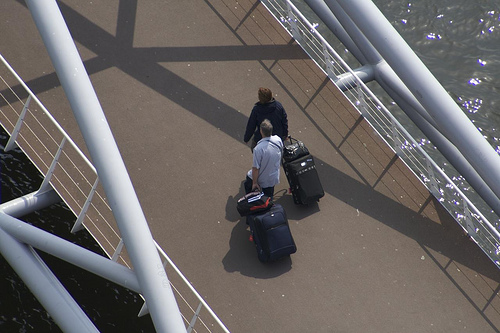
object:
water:
[290, 0, 499, 237]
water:
[0, 124, 157, 333]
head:
[258, 118, 274, 137]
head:
[257, 86, 274, 105]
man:
[241, 84, 290, 155]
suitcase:
[282, 152, 327, 207]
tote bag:
[234, 188, 274, 218]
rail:
[0, 0, 190, 332]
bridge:
[1, 1, 500, 333]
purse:
[280, 134, 311, 163]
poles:
[0, 226, 107, 332]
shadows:
[0, 54, 119, 109]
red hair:
[257, 86, 274, 104]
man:
[241, 118, 285, 202]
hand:
[250, 182, 262, 192]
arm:
[248, 146, 264, 184]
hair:
[257, 116, 275, 138]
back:
[254, 134, 285, 189]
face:
[258, 121, 264, 137]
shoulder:
[251, 139, 270, 152]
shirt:
[245, 134, 284, 190]